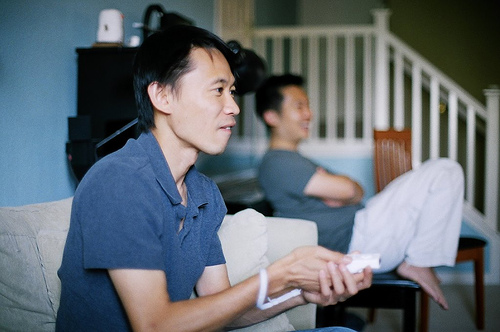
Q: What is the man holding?
A: Game control.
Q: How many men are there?
A: 2.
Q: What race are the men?
A: Asian.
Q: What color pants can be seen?
A: White.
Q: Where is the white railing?
A: Stairwell.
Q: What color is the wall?
A: Blue.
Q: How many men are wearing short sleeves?
A: 2.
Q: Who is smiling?
A: The man with legs up.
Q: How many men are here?
A: Two.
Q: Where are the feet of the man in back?
A: On the chair.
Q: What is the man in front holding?
A: A controller.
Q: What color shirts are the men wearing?
A: Blue.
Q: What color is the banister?
A: White.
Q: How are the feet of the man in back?
A: Bare.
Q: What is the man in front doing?
A: Playing a video game.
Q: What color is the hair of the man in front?
A: Black.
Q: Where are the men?
A: In the living room.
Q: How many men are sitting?
A: Two.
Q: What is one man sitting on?
A: A couch.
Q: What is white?
A: Stair railings.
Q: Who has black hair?
A: Two men.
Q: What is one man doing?
A: Playing video game.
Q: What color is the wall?
A: Blue.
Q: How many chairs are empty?
A: One.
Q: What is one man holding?
A: Game controller.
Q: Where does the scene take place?
A: In a living room.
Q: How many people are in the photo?
A: Two.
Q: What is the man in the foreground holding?
A: Wii remote.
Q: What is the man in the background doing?
A: Laughing.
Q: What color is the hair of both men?
A: Black.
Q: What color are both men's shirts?
A: Blue.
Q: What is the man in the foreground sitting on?
A: Tan sofa.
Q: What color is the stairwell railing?
A: White.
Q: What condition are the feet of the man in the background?
A: Barefoot.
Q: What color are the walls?
A: Blue.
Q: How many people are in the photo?
A: Two.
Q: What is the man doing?
A: Playing video game.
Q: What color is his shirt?
A: Blue.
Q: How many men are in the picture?
A: Two.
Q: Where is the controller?
A: In his hands.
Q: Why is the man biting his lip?
A: He's concentrating.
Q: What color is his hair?
A: Black.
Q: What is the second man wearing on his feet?
A: Nothing.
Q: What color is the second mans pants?
A: Tan.